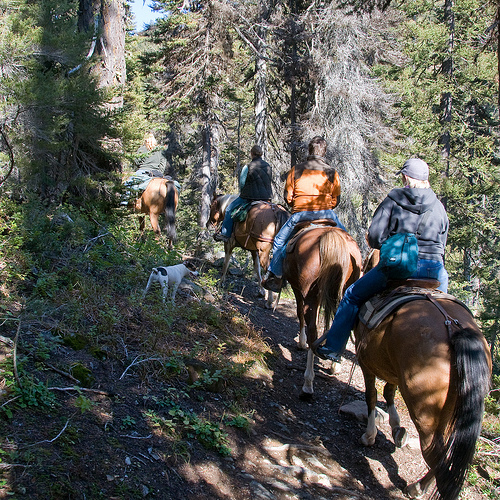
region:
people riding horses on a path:
[129, 107, 497, 492]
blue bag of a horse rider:
[377, 230, 425, 283]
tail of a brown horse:
[436, 329, 486, 499]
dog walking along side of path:
[127, 250, 214, 309]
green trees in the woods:
[420, 13, 495, 155]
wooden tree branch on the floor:
[116, 348, 163, 385]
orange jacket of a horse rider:
[282, 162, 347, 212]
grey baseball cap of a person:
[392, 153, 438, 180]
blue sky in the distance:
[132, 2, 154, 23]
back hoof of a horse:
[295, 380, 325, 406]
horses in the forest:
[86, 74, 493, 382]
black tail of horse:
[438, 330, 498, 475]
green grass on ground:
[144, 351, 239, 469]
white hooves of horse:
[337, 399, 404, 469]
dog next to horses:
[136, 253, 209, 322]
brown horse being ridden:
[353, 296, 451, 388]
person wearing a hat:
[375, 151, 457, 258]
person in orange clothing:
[278, 135, 350, 232]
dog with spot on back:
[137, 256, 212, 321]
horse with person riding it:
[96, 130, 183, 222]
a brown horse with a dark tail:
[353, 245, 498, 497]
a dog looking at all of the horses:
[143, 260, 204, 302]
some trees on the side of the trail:
[300, 35, 498, 175]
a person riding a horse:
[266, 128, 343, 269]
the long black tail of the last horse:
[443, 322, 485, 494]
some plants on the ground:
[9, 219, 229, 431]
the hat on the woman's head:
[395, 155, 430, 183]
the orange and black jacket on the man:
[286, 156, 341, 215]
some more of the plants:
[33, 218, 151, 340]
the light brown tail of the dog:
[303, 227, 355, 344]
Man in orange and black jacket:
[277, 134, 344, 226]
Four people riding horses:
[30, 136, 498, 479]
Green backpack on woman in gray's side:
[376, 215, 436, 291]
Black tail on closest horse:
[410, 324, 499, 498]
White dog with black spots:
[141, 255, 199, 304]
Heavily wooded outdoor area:
[47, 53, 287, 413]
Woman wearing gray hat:
[370, 151, 451, 261]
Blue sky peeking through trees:
[105, 5, 224, 40]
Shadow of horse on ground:
[250, 339, 394, 492]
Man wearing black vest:
[230, 134, 275, 202]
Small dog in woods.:
[116, 250, 196, 333]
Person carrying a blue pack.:
[333, 179, 448, 306]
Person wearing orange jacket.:
[247, 171, 358, 252]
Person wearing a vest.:
[201, 121, 280, 266]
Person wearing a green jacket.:
[121, 118, 184, 235]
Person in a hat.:
[372, 140, 452, 216]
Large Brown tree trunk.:
[63, 6, 152, 179]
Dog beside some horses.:
[78, 202, 448, 317]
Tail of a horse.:
[397, 331, 492, 493]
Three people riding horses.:
[213, 126, 482, 423]